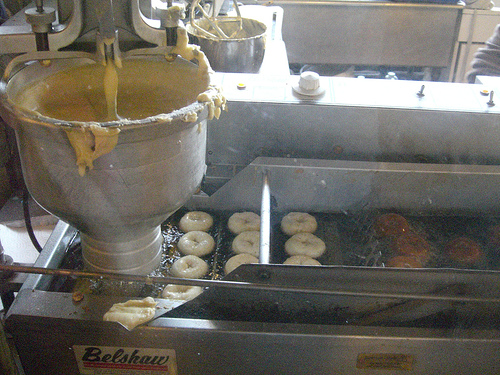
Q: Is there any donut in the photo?
A: Yes, there is a donut.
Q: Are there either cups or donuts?
A: Yes, there is a donut.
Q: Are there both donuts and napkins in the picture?
A: No, there is a donut but no napkins.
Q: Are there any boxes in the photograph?
A: No, there are no boxes.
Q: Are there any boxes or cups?
A: No, there are no boxes or cups.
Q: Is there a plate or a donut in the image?
A: Yes, there is a donut.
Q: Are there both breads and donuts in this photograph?
A: No, there is a donut but no breads.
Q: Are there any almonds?
A: No, there are no almonds.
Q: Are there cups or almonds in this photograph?
A: No, there are no almonds or cups.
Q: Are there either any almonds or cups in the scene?
A: No, there are no almonds or cups.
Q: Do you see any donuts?
A: Yes, there is a donut.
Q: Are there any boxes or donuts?
A: Yes, there is a donut.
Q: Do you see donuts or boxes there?
A: Yes, there is a donut.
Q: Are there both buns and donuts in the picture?
A: No, there is a donut but no buns.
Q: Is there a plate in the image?
A: No, there are no plates.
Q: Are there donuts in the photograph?
A: Yes, there is a donut.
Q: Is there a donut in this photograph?
A: Yes, there is a donut.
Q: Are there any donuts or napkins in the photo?
A: Yes, there is a donut.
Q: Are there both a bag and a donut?
A: No, there is a donut but no bags.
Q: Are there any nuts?
A: No, there are no nuts.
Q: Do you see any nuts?
A: No, there are no nuts.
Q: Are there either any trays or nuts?
A: No, there are no nuts or trays.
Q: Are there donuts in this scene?
A: Yes, there is a donut.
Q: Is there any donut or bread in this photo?
A: Yes, there is a donut.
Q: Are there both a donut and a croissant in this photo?
A: No, there is a donut but no croissants.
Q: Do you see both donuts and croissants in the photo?
A: No, there is a donut but no croissants.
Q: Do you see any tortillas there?
A: No, there are no tortillas.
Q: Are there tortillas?
A: No, there are no tortillas.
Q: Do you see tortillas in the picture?
A: No, there are no tortillas.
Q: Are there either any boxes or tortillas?
A: No, there are no tortillas or boxes.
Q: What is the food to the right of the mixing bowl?
A: The food is a donut.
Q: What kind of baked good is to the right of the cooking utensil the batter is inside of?
A: The food is a donut.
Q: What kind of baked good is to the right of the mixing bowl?
A: The food is a donut.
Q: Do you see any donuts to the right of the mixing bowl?
A: Yes, there is a donut to the right of the mixing bowl.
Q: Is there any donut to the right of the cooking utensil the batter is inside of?
A: Yes, there is a donut to the right of the mixing bowl.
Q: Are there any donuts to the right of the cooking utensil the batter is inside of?
A: Yes, there is a donut to the right of the mixing bowl.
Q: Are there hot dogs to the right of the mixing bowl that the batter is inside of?
A: No, there is a donut to the right of the mixing bowl.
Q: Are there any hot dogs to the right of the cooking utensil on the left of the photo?
A: No, there is a donut to the right of the mixing bowl.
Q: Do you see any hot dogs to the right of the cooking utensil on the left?
A: No, there is a donut to the right of the mixing bowl.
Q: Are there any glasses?
A: No, there are no glasses.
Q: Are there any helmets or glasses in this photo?
A: No, there are no glasses or helmets.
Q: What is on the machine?
A: The sticker is on the machine.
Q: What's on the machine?
A: The sticker is on the machine.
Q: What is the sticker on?
A: The sticker is on the machine.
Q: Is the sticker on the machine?
A: Yes, the sticker is on the machine.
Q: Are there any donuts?
A: Yes, there is a donut.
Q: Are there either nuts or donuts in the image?
A: Yes, there is a donut.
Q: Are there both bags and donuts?
A: No, there is a donut but no bags.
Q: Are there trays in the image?
A: No, there are no trays.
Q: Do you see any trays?
A: No, there are no trays.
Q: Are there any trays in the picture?
A: No, there are no trays.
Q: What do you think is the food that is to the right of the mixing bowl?
A: The food is a donut.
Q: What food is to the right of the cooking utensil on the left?
A: The food is a donut.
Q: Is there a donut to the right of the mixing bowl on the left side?
A: Yes, there is a donut to the right of the mixing bowl.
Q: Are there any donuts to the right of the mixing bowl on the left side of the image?
A: Yes, there is a donut to the right of the mixing bowl.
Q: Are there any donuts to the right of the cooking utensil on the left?
A: Yes, there is a donut to the right of the mixing bowl.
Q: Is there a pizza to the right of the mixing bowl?
A: No, there is a donut to the right of the mixing bowl.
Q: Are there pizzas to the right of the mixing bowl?
A: No, there is a donut to the right of the mixing bowl.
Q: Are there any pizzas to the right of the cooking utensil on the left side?
A: No, there is a donut to the right of the mixing bowl.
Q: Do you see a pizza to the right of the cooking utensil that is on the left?
A: No, there is a donut to the right of the mixing bowl.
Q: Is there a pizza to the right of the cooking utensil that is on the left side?
A: No, there is a donut to the right of the mixing bowl.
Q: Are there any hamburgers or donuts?
A: Yes, there is a donut.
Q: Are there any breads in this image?
A: No, there are no breads.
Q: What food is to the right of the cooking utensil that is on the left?
A: The food is a donut.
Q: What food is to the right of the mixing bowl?
A: The food is a donut.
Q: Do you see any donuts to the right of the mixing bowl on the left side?
A: Yes, there is a donut to the right of the mixing bowl.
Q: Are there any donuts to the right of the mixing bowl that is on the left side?
A: Yes, there is a donut to the right of the mixing bowl.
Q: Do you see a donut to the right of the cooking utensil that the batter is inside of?
A: Yes, there is a donut to the right of the mixing bowl.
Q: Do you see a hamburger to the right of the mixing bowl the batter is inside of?
A: No, there is a donut to the right of the mixing bowl.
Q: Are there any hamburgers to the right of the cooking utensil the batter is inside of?
A: No, there is a donut to the right of the mixing bowl.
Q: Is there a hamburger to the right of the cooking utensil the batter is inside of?
A: No, there is a donut to the right of the mixing bowl.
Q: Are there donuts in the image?
A: Yes, there is a donut.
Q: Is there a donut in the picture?
A: Yes, there is a donut.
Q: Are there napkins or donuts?
A: Yes, there is a donut.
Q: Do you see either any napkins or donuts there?
A: Yes, there is a donut.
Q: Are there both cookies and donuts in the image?
A: No, there is a donut but no cookies.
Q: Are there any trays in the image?
A: No, there are no trays.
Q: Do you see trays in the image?
A: No, there are no trays.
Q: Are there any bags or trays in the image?
A: No, there are no trays or bags.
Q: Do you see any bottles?
A: No, there are no bottles.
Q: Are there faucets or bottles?
A: No, there are no bottles or faucets.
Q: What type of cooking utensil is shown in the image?
A: The cooking utensil is a mixing bowl.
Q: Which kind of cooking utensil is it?
A: The cooking utensil is a mixing bowl.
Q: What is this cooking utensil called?
A: That is a mixing bowl.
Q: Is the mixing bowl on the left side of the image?
A: Yes, the mixing bowl is on the left of the image.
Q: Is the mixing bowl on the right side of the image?
A: No, the mixing bowl is on the left of the image.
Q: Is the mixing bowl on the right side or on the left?
A: The mixing bowl is on the left of the image.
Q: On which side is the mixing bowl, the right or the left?
A: The mixing bowl is on the left of the image.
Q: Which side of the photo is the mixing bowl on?
A: The mixing bowl is on the left of the image.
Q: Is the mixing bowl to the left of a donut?
A: Yes, the mixing bowl is to the left of a donut.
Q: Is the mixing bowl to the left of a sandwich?
A: No, the mixing bowl is to the left of a donut.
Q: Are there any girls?
A: No, there are no girls.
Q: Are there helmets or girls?
A: No, there are no girls or helmets.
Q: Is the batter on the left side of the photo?
A: Yes, the batter is on the left of the image.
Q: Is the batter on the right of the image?
A: No, the batter is on the left of the image.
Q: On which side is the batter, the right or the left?
A: The batter is on the left of the image.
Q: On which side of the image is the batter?
A: The batter is on the left of the image.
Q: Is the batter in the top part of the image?
A: Yes, the batter is in the top of the image.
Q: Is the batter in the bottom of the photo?
A: No, the batter is in the top of the image.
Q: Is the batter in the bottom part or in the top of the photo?
A: The batter is in the top of the image.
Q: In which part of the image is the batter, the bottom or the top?
A: The batter is in the top of the image.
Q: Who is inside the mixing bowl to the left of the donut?
A: The batter is inside the mixing bowl.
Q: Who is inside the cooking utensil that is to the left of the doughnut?
A: The batter is inside the mixing bowl.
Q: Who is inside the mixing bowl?
A: The batter is inside the mixing bowl.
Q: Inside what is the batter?
A: The batter is inside the mixing bowl.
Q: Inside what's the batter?
A: The batter is inside the mixing bowl.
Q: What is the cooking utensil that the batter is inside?
A: The cooking utensil is a mixing bowl.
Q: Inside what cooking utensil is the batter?
A: The batter is inside the mixing bowl.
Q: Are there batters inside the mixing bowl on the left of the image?
A: Yes, there is a batter inside the mixing bowl.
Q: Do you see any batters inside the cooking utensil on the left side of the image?
A: Yes, there is a batter inside the mixing bowl.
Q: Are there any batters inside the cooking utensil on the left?
A: Yes, there is a batter inside the mixing bowl.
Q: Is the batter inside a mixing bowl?
A: Yes, the batter is inside a mixing bowl.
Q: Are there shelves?
A: No, there are no shelves.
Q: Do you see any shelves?
A: No, there are no shelves.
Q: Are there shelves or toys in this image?
A: No, there are no shelves or toys.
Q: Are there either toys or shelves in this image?
A: No, there are no shelves or toys.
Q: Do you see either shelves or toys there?
A: No, there are no shelves or toys.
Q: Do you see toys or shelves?
A: No, there are no shelves or toys.